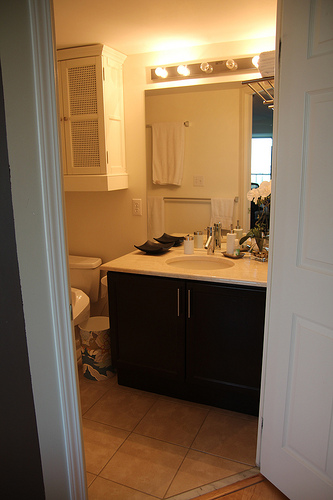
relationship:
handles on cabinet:
[177, 290, 192, 320] [106, 274, 266, 417]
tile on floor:
[100, 434, 187, 499] [78, 372, 258, 497]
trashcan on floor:
[79, 317, 112, 372] [78, 372, 258, 497]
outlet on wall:
[133, 198, 145, 219] [59, 53, 152, 270]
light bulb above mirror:
[249, 56, 262, 70] [248, 92, 273, 196]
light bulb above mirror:
[225, 60, 239, 74] [248, 92, 273, 196]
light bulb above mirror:
[200, 62, 216, 78] [248, 92, 273, 196]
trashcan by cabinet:
[79, 317, 112, 372] [106, 274, 266, 417]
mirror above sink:
[248, 92, 273, 196] [168, 256, 230, 274]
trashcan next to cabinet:
[79, 317, 112, 372] [106, 274, 266, 417]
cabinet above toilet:
[51, 41, 129, 194] [67, 257, 101, 360]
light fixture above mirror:
[148, 55, 268, 82] [248, 92, 273, 196]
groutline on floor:
[163, 450, 189, 499] [78, 372, 258, 497]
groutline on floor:
[95, 433, 131, 478] [78, 372, 258, 497]